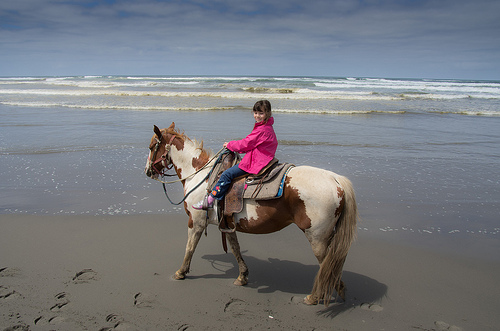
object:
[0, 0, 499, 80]
clouds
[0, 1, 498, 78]
sky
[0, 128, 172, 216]
section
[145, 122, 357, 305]
horse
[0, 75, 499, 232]
lake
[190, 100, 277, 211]
girl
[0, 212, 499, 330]
beach